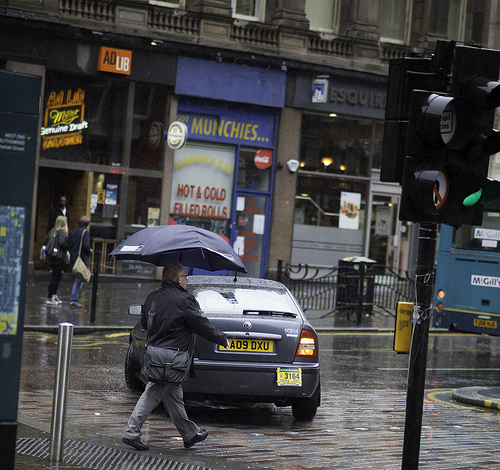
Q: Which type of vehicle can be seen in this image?
A: The vehicle is a car.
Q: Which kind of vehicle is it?
A: The vehicle is a car.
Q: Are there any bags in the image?
A: Yes, there is a bag.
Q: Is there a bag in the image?
A: Yes, there is a bag.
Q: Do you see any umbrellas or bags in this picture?
A: Yes, there is a bag.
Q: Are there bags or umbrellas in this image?
A: Yes, there is a bag.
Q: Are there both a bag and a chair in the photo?
A: No, there is a bag but no chairs.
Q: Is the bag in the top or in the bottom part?
A: The bag is in the bottom of the image.